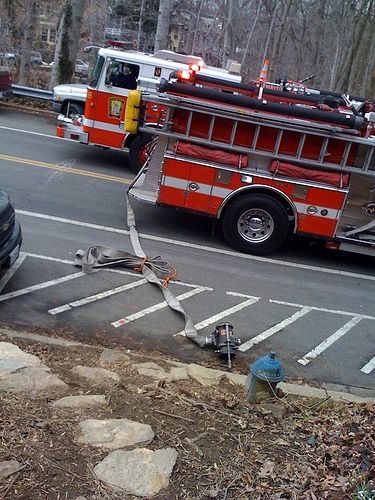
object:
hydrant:
[245, 349, 289, 409]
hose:
[72, 144, 210, 350]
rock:
[89, 445, 177, 498]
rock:
[73, 415, 153, 449]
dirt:
[1, 333, 371, 499]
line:
[1, 153, 133, 185]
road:
[2, 124, 368, 283]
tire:
[217, 191, 290, 259]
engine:
[121, 67, 375, 257]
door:
[93, 55, 140, 149]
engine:
[55, 41, 375, 177]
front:
[53, 45, 104, 151]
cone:
[258, 56, 271, 85]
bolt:
[268, 346, 278, 360]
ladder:
[130, 90, 375, 177]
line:
[10, 205, 374, 280]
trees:
[47, 2, 87, 109]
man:
[108, 65, 139, 92]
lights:
[175, 66, 195, 81]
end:
[119, 65, 176, 203]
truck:
[48, 79, 93, 124]